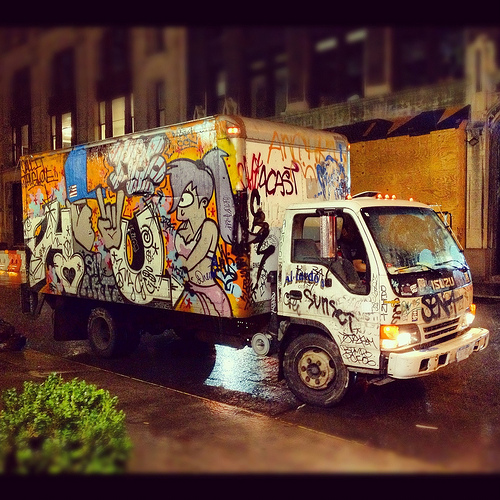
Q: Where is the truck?
A: On the road.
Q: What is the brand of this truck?
A: Isuzu.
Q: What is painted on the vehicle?
A: A girl on the truck.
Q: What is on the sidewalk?
A: A bush.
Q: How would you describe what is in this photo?
A: A white box truck covered with graffiti.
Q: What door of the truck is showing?
A: The passenger door.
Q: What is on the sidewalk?
A: A bush.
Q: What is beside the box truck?
A: A sidewalk.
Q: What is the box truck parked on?
A: The street.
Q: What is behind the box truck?
A: Buildings.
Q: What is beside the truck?
A: Boarded-up windows of storefront.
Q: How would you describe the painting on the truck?
A: It has graffiti on it.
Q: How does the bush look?
A: It is green and leafy.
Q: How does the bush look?
A: It is green.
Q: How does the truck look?
A: It is colorful.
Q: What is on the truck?
A: It has graffiti.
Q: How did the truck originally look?
A: It was white.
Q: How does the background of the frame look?
A: It is blurry.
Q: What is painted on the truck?
A: A cartoon character.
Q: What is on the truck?
A: Paintings.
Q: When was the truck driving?
A: Nighttime.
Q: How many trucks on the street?
A: One.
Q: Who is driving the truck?
A: A person.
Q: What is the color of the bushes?
A: Green.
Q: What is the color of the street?
A: Gray.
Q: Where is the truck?
A: On the street.